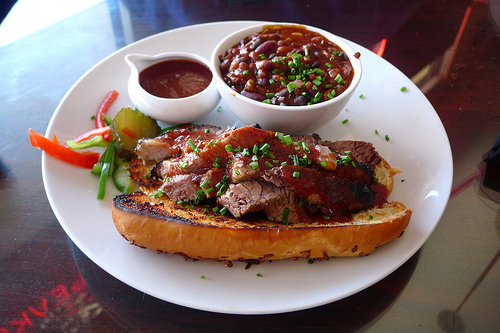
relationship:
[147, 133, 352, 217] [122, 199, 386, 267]
meat on bread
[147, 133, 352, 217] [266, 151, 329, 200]
meat has sauce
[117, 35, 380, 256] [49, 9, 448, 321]
food on plate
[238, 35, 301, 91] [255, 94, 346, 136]
beans in bowl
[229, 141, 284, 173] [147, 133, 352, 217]
parsley on meat